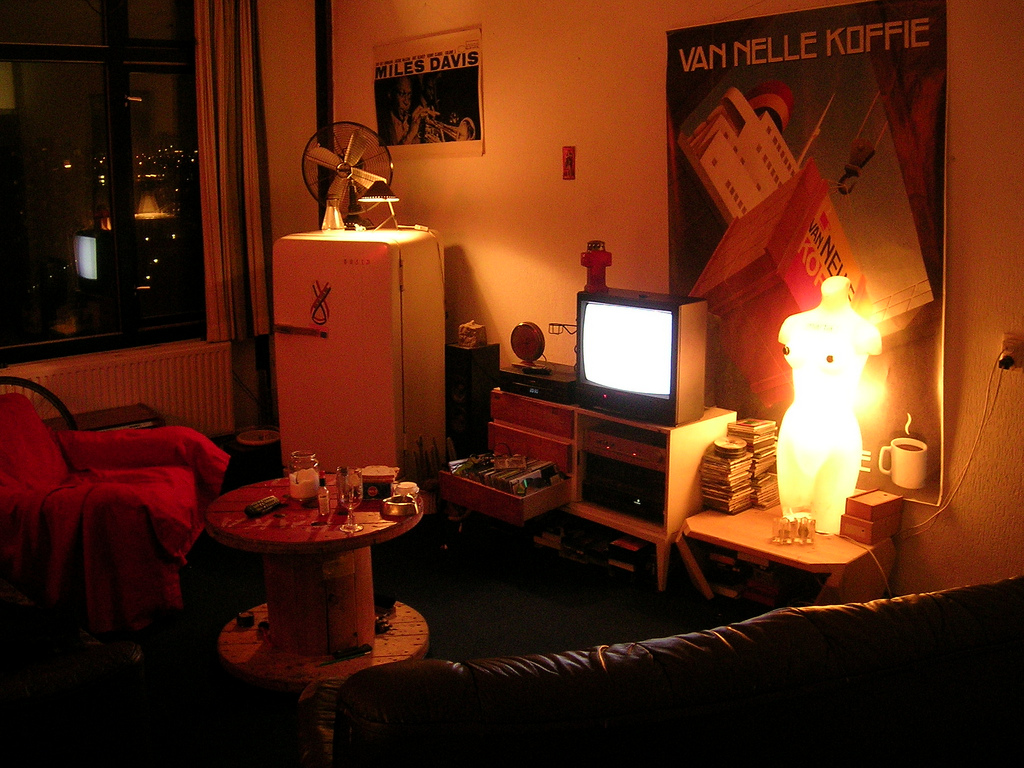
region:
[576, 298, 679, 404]
a tv that is on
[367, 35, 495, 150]
a miles davis poster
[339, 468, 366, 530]
a glass wine glass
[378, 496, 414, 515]
a silver metal ashtray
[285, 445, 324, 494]
a white wax candle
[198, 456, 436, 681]
a wooden circle table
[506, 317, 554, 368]
a standing clock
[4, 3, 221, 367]
a large glass window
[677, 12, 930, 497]
large poster on apartment wall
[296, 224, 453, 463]
small white fridge in apartment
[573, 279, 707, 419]
small television turned on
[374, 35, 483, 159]
small poster on apartment wall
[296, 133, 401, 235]
small fan above refrigerator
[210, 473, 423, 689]
round wooden table in apartment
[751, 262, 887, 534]
illuminated torso lamp by poster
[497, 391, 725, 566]
wooden cabinet under tv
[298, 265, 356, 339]
small ribbon sticker on fridge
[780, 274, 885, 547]
Illuminated mannequin on a table.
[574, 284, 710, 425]
Black television with white screen.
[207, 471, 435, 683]
Large round wooden spool.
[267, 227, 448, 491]
A white refridgerator.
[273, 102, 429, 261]
the fan is off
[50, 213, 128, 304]
teh Tv reflected on the window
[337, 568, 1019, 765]
the couch is color black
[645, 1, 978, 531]
a big poster begind the TV and lamp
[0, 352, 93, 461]
teh wheel of a bike behind the chair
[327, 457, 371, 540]
a glass on a table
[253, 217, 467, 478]
the refrigerator is white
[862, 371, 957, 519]
picture of a cup on a poster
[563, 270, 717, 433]
the TV is turn on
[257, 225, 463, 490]
a refrigerator in a living room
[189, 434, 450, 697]
the center table is round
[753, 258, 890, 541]
a lamp in form of a woman body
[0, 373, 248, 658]
the chair is covered with a red fabric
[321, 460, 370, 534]
a glass on a table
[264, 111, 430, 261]
a fan on a refrigerator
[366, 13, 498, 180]
a board on the wall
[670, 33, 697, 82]
A letter on a sign.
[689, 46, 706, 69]
A letter on a sign.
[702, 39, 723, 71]
A letter on a sign.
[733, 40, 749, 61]
A letter on a sign.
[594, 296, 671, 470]
a tv on the stand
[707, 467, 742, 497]
a cd case on the table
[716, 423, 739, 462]
a cd case on the table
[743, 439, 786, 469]
a cd case on the table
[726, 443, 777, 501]
a cd case on the table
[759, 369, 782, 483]
a cd case on the table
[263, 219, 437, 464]
a white refridgerator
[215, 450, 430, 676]
a round wood table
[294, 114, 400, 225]
a electrical fan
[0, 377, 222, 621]
a chair covered with a blanket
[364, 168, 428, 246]
a small black lamp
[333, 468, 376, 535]
a clear wine glass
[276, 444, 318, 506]
a white candle in a glass jar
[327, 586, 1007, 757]
a brown leather couch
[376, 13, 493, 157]
a poster hanging on a wall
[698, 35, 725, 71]
A letter on a sign.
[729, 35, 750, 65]
A letter on a sign.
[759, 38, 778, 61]
A letter on a sign.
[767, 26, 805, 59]
A letter on a sign.